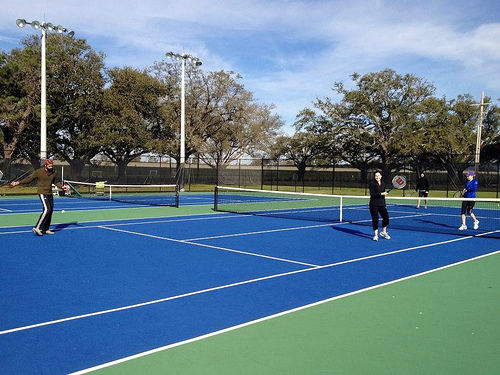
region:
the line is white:
[154, 194, 279, 339]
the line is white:
[200, 261, 295, 355]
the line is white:
[230, 231, 340, 352]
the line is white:
[105, 68, 277, 371]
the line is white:
[163, 279, 244, 352]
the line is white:
[233, 288, 305, 358]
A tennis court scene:
[6, 10, 492, 363]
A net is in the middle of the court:
[209, 172, 499, 247]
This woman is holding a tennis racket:
[366, 162, 408, 247]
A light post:
[160, 40, 208, 185]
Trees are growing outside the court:
[5, 34, 492, 162]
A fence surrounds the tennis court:
[71, 150, 351, 195]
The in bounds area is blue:
[181, 247, 323, 300]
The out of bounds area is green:
[347, 305, 469, 362]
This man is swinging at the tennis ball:
[2, 155, 82, 245]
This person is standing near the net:
[453, 167, 487, 243]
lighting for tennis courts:
[13, 12, 85, 154]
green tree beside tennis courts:
[93, 58, 163, 177]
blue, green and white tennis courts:
[84, 175, 296, 374]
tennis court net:
[213, 180, 340, 237]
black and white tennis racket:
[383, 157, 408, 209]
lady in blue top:
[456, 162, 482, 239]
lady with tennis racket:
[351, 162, 426, 252]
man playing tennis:
[7, 135, 85, 249]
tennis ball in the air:
[57, 205, 67, 218]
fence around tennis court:
[201, 149, 314, 196]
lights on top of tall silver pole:
[22, 17, 72, 189]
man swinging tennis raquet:
[10, 156, 77, 241]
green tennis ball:
[60, 207, 66, 214]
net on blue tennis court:
[213, 187, 496, 227]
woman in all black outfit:
[366, 166, 400, 248]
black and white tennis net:
[57, 178, 174, 204]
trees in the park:
[1, 37, 498, 169]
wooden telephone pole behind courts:
[472, 89, 480, 163]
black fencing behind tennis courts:
[21, 151, 488, 187]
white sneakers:
[373, 232, 387, 238]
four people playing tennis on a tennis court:
[7, 5, 494, 369]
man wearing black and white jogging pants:
[12, 141, 113, 264]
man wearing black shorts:
[407, 157, 439, 217]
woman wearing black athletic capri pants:
[344, 148, 421, 259]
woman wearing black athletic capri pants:
[447, 153, 496, 233]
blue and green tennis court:
[102, 190, 327, 350]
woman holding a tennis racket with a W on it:
[351, 146, 424, 249]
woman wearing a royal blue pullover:
[447, 147, 495, 248]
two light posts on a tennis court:
[19, 10, 209, 253]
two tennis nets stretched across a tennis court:
[65, 167, 498, 239]